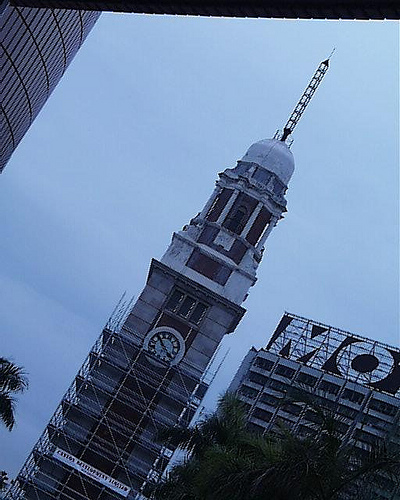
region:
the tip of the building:
[272, 28, 373, 153]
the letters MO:
[266, 296, 398, 400]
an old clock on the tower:
[122, 301, 203, 378]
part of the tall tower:
[63, 275, 256, 390]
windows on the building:
[256, 343, 397, 451]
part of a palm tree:
[0, 318, 70, 431]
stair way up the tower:
[54, 348, 214, 471]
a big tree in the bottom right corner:
[131, 369, 399, 499]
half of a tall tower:
[111, 97, 309, 371]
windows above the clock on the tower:
[152, 273, 228, 342]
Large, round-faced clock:
[140, 326, 186, 371]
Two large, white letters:
[264, 309, 395, 386]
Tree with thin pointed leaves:
[147, 379, 399, 498]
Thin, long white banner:
[50, 443, 131, 497]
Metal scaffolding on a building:
[2, 291, 234, 498]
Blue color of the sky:
[101, 18, 240, 137]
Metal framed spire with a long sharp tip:
[273, 43, 345, 149]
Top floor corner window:
[250, 350, 278, 376]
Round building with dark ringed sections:
[1, 0, 106, 177]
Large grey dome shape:
[236, 135, 298, 189]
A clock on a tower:
[138, 322, 187, 371]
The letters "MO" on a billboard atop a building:
[268, 317, 394, 381]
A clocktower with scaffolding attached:
[40, 249, 249, 499]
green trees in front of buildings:
[162, 389, 396, 499]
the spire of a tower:
[164, 64, 296, 296]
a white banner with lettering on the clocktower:
[49, 451, 130, 499]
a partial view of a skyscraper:
[4, 4, 96, 180]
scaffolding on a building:
[12, 297, 196, 497]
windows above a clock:
[164, 284, 212, 328]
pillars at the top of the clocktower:
[205, 181, 273, 241]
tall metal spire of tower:
[274, 49, 341, 123]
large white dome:
[221, 137, 306, 187]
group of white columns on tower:
[188, 182, 287, 252]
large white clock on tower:
[142, 324, 186, 368]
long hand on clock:
[156, 335, 166, 348]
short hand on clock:
[163, 349, 174, 358]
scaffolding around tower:
[78, 348, 184, 453]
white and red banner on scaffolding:
[48, 448, 134, 497]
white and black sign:
[254, 293, 398, 413]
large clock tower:
[36, 59, 350, 460]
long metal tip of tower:
[270, 48, 338, 142]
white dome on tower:
[232, 137, 307, 185]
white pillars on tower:
[212, 189, 268, 237]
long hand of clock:
[153, 329, 166, 348]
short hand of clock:
[162, 347, 172, 359]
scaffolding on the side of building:
[45, 352, 195, 478]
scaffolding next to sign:
[257, 315, 391, 417]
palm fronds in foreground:
[149, 396, 341, 498]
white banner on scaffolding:
[46, 445, 134, 498]